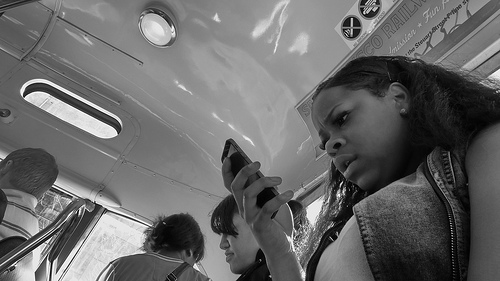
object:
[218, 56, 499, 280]
girl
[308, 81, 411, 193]
face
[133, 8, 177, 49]
light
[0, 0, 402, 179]
ceiling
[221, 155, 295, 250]
hand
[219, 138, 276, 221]
phone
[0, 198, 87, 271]
safety bar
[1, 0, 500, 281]
bus